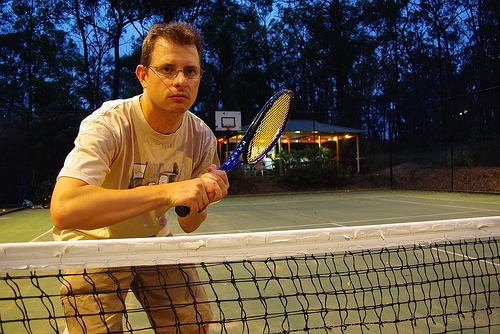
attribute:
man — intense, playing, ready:
[47, 21, 231, 333]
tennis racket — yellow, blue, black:
[176, 87, 295, 217]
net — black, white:
[0, 216, 500, 333]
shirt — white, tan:
[53, 93, 221, 240]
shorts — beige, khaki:
[62, 237, 213, 333]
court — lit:
[18, 190, 499, 333]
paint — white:
[29, 222, 57, 244]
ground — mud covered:
[382, 167, 500, 194]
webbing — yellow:
[248, 93, 292, 163]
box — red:
[220, 115, 237, 128]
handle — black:
[177, 204, 191, 218]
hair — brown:
[140, 22, 203, 68]